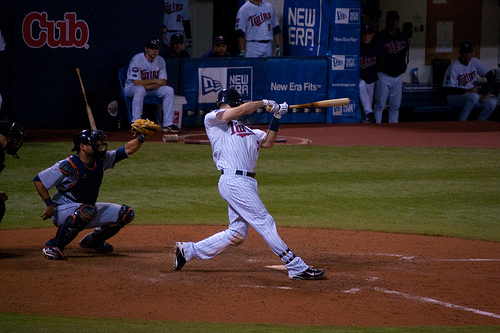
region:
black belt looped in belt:
[211, 163, 271, 185]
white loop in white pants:
[203, 159, 268, 181]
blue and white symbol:
[194, 61, 265, 116]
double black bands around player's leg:
[263, 245, 305, 268]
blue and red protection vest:
[51, 143, 95, 184]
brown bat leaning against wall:
[64, 57, 106, 135]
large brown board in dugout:
[417, 5, 477, 71]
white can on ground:
[158, 132, 188, 148]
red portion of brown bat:
[281, 95, 336, 122]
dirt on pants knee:
[225, 229, 251, 258]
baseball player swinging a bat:
[201, 68, 312, 293]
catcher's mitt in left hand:
[134, 113, 163, 151]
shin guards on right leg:
[61, 198, 92, 261]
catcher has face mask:
[86, 123, 109, 178]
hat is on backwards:
[61, 130, 97, 147]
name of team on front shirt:
[233, 118, 260, 146]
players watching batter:
[361, 29, 498, 130]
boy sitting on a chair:
[116, 21, 188, 141]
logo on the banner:
[281, 3, 333, 70]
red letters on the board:
[18, 8, 108, 56]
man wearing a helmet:
[165, 77, 350, 287]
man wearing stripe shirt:
[162, 80, 342, 295]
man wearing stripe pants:
[155, 77, 360, 313]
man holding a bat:
[167, 77, 347, 300]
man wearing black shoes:
[161, 73, 322, 293]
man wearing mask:
[26, 112, 162, 263]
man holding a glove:
[26, 105, 163, 271]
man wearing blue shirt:
[10, 115, 161, 256]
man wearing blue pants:
[18, 110, 154, 276]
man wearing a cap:
[114, 36, 190, 111]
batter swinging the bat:
[165, 74, 365, 285]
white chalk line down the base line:
[369, 271, 483, 324]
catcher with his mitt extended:
[27, 112, 165, 256]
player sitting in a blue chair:
[119, 36, 176, 131]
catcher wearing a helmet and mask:
[70, 126, 110, 161]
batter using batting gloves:
[259, 91, 290, 128]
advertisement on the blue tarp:
[281, 2, 318, 54]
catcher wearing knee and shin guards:
[56, 200, 136, 252]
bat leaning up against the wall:
[64, 63, 102, 137]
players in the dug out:
[361, 15, 496, 130]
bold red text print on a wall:
[15, 7, 99, 54]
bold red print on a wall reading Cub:
[16, 9, 96, 51]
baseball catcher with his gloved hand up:
[26, 118, 181, 261]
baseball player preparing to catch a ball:
[28, 114, 174, 259]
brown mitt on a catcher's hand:
[128, 116, 164, 138]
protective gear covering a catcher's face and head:
[68, 125, 110, 162]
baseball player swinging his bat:
[172, 86, 355, 281]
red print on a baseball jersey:
[223, 118, 257, 138]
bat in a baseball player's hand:
[257, 96, 356, 111]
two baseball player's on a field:
[30, 86, 357, 282]